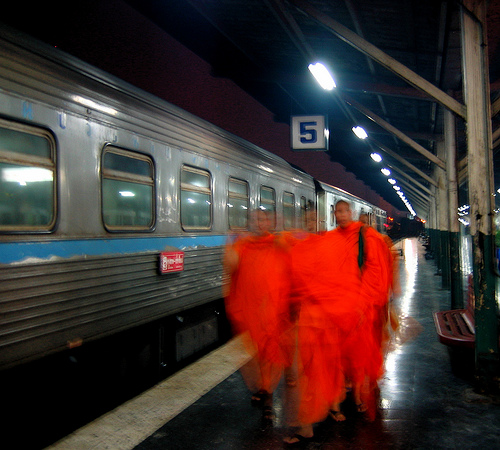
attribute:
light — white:
[302, 54, 341, 95]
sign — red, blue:
[166, 250, 189, 284]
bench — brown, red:
[441, 273, 485, 340]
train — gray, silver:
[21, 69, 155, 334]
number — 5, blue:
[284, 107, 325, 151]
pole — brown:
[470, 36, 488, 215]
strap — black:
[355, 222, 376, 271]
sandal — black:
[277, 418, 320, 449]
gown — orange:
[289, 226, 346, 403]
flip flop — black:
[269, 412, 316, 443]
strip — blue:
[71, 224, 97, 258]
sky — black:
[222, 41, 246, 77]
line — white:
[171, 354, 211, 394]